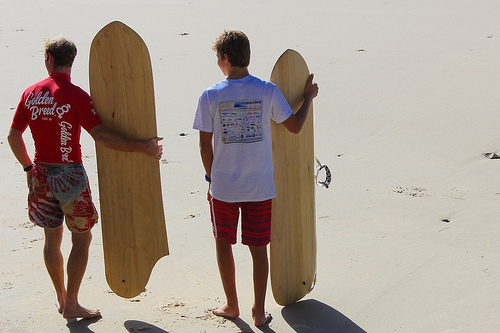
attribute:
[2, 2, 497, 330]
sand — very white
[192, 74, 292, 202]
t-shirt — white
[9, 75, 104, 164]
shirt — red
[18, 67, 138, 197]
shirt — red and white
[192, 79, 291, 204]
shirt — white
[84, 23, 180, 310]
surfboard — makeshift, uneven, wooden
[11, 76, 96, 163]
red shirt — red s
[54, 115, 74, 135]
letter — white 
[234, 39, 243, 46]
hair — short, brown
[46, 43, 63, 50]
hair — brown, short